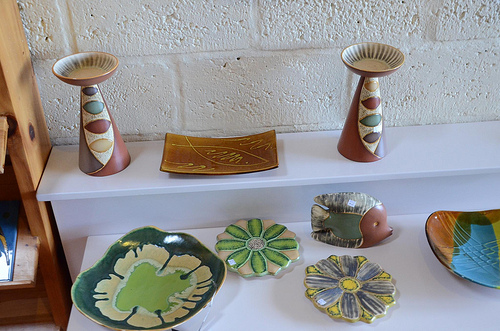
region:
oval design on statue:
[82, 87, 99, 97]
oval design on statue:
[83, 98, 105, 116]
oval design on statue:
[84, 119, 113, 132]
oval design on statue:
[88, 138, 113, 155]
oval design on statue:
[364, 80, 378, 90]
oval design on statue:
[358, 94, 379, 111]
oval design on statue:
[356, 110, 381, 127]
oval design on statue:
[361, 131, 380, 142]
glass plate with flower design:
[213, 215, 300, 280]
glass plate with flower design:
[303, 252, 393, 323]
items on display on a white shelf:
[35, 34, 487, 328]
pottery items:
[55, 26, 483, 326]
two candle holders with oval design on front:
[58, 32, 420, 182]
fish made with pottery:
[305, 189, 400, 249]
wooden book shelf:
[0, 0, 62, 323]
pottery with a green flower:
[225, 207, 306, 280]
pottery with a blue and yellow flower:
[295, 249, 402, 322]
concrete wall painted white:
[56, 4, 482, 136]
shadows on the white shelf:
[202, 264, 309, 327]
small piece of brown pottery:
[155, 125, 282, 183]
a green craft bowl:
[71, 226, 225, 329]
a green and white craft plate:
[217, 215, 299, 275]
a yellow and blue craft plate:
[305, 250, 397, 325]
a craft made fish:
[310, 189, 393, 246]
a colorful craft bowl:
[422, 208, 499, 292]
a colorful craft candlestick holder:
[51, 50, 132, 176]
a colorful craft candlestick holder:
[336, 42, 407, 165]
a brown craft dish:
[158, 130, 278, 177]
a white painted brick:
[172, 49, 348, 132]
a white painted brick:
[351, 42, 498, 126]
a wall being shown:
[6, 0, 498, 122]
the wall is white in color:
[21, 3, 498, 128]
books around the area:
[0, 193, 46, 286]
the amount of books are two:
[0, 196, 45, 292]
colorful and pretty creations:
[46, 40, 489, 310]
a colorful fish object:
[311, 189, 396, 249]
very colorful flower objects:
[205, 220, 407, 316]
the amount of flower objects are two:
[215, 210, 396, 322]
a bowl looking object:
[60, 225, 225, 320]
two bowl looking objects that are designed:
[64, 200, 495, 330]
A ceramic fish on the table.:
[285, 193, 406, 263]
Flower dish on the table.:
[291, 261, 413, 322]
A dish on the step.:
[151, 117, 295, 181]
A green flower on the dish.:
[223, 209, 287, 266]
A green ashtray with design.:
[66, 232, 246, 315]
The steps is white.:
[13, 158, 475, 228]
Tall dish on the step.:
[53, 52, 125, 176]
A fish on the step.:
[302, 192, 410, 244]